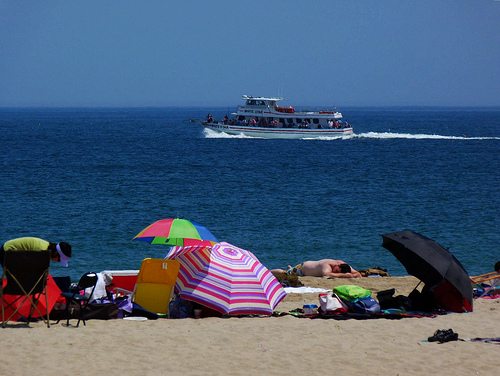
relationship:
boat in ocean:
[192, 90, 375, 161] [152, 138, 247, 206]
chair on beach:
[142, 260, 193, 321] [215, 304, 286, 374]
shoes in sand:
[424, 325, 463, 349] [308, 337, 340, 359]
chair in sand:
[142, 260, 193, 321] [308, 337, 340, 359]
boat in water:
[192, 90, 375, 161] [74, 98, 116, 139]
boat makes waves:
[192, 90, 375, 161] [363, 120, 398, 151]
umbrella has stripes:
[384, 222, 468, 302] [215, 255, 237, 280]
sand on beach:
[308, 337, 340, 359] [215, 304, 286, 374]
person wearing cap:
[11, 222, 82, 265] [60, 252, 66, 264]